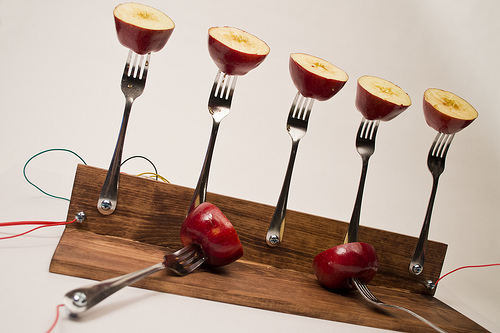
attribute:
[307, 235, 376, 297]
apple — red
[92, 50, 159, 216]
fork — silver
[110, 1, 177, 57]
apple — red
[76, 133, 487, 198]
forks — metal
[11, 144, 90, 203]
wire — green, teal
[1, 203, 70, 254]
wire — red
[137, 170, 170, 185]
wire — yellow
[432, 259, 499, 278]
cord — red